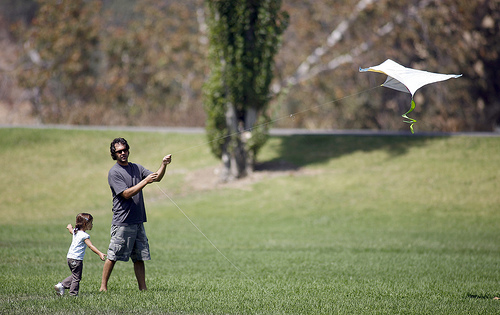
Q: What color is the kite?
A: White.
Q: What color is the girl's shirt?
A: White.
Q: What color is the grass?
A: Green.